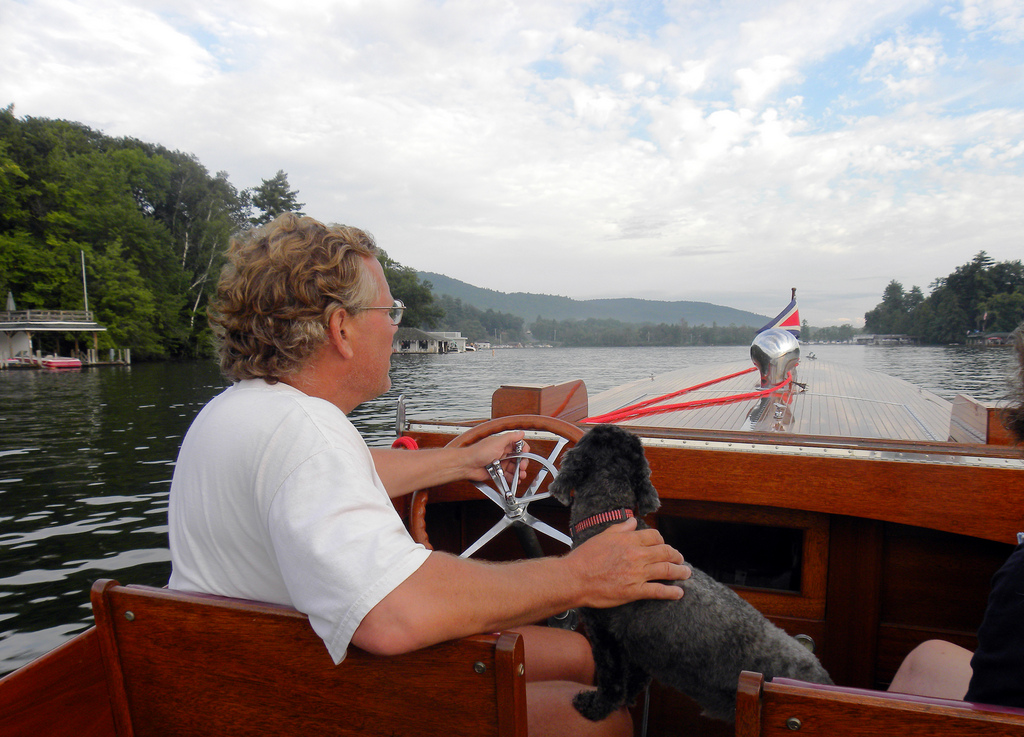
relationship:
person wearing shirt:
[165, 212, 694, 647] [166, 377, 428, 663]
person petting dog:
[165, 212, 694, 647] [556, 424, 837, 731]